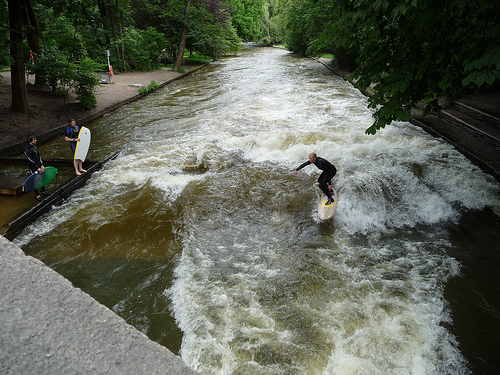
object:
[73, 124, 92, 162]
board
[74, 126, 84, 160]
yellow edging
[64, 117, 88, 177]
person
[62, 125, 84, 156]
wetsuit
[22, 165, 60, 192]
board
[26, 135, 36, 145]
dark hair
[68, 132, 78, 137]
black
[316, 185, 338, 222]
surfboard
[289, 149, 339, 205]
person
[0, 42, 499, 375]
water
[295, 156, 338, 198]
wetsuit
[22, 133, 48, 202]
person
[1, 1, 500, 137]
background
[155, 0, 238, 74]
trees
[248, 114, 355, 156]
waves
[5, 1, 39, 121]
trunk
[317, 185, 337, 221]
grey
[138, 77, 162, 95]
grass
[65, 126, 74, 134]
blue